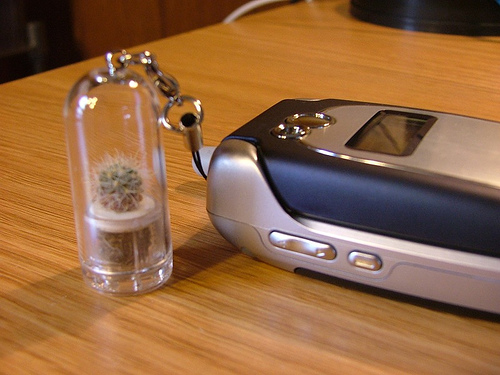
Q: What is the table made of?
A: Wood.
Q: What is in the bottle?
A: Cactus.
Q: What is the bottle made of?
A: Glass.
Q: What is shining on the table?
A: Light.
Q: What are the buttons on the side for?
A: Volume.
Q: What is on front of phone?
A: Screen.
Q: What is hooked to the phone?
A: Chain.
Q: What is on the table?
A: A phone.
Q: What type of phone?
A: A cell phone.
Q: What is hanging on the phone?
A: A keychain.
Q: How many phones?
A: 1.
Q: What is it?
A: Keychain.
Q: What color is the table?
A: Brown.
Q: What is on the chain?
A: Decoration.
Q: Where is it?
A: On the table.